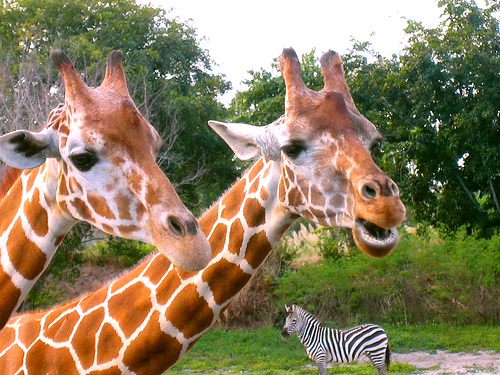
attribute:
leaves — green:
[345, 32, 360, 43]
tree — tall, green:
[0, 0, 232, 266]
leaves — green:
[0, 0, 234, 214]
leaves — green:
[442, 185, 464, 217]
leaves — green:
[405, 73, 455, 146]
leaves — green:
[442, 79, 489, 109]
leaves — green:
[415, 75, 438, 100]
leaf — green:
[144, 51, 147, 54]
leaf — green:
[157, 56, 160, 61]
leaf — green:
[160, 38, 164, 42]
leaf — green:
[169, 46, 175, 50]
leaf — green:
[160, 68, 165, 70]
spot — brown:
[243, 230, 272, 268]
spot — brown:
[242, 194, 267, 228]